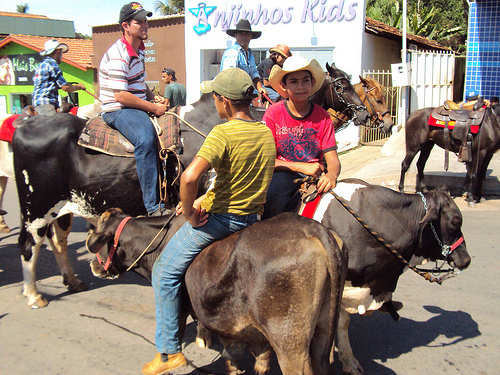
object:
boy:
[261, 55, 343, 220]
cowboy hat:
[267, 55, 326, 99]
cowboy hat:
[226, 19, 261, 40]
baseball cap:
[118, 2, 153, 23]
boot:
[140, 350, 188, 374]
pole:
[397, 0, 408, 153]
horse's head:
[311, 61, 370, 125]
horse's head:
[326, 74, 392, 132]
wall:
[462, 0, 500, 103]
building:
[0, 0, 500, 113]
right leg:
[17, 179, 61, 286]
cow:
[10, 112, 207, 310]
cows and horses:
[13, 61, 500, 375]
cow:
[87, 207, 347, 375]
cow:
[286, 177, 470, 375]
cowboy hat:
[38, 38, 70, 56]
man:
[98, 1, 171, 218]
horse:
[397, 94, 499, 209]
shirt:
[192, 118, 276, 216]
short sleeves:
[192, 134, 227, 171]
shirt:
[30, 58, 67, 109]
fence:
[360, 69, 402, 147]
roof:
[0, 31, 96, 72]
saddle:
[427, 94, 499, 172]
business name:
[188, 0, 359, 36]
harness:
[76, 105, 180, 158]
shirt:
[259, 99, 337, 170]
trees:
[365, 0, 469, 47]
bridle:
[287, 172, 464, 286]